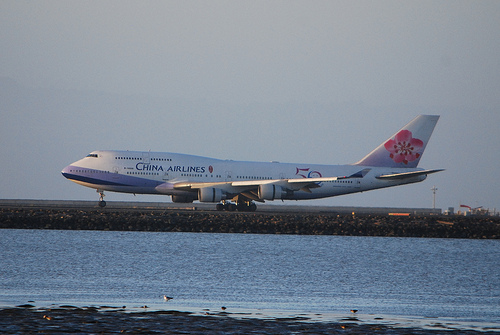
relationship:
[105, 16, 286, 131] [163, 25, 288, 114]
cloudless blue sky clear blue sky clear blue sky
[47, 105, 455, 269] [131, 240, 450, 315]
plane on landing are by water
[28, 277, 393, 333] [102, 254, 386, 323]
birds along edge of water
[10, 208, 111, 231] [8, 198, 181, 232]
rocks on side of landing area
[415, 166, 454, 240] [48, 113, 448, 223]
airport tower behind plane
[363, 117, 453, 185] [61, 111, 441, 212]
red logo on tail of airplane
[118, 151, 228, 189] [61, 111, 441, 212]
airline logo on left side of airplane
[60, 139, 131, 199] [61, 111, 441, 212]
windows on the left of airplane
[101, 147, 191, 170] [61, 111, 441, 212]
small windows of airplane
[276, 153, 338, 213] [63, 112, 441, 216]
number 50 side of plane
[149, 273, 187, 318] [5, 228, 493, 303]
seagull in water sitting in water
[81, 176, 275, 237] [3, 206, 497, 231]
wheels on runway on runway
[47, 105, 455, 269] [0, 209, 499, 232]
airplane on ground on ground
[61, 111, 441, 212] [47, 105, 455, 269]
airplane in front of in front of water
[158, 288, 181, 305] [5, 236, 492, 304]
seagull in water in water